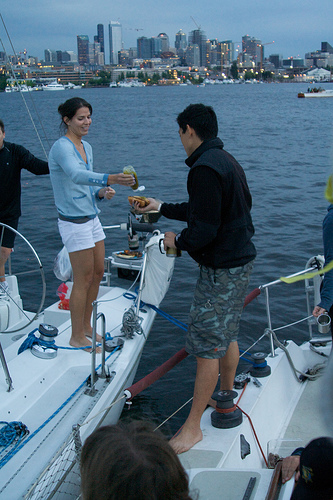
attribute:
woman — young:
[41, 101, 135, 348]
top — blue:
[47, 141, 105, 218]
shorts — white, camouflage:
[46, 217, 119, 251]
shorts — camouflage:
[189, 268, 248, 360]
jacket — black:
[159, 152, 277, 269]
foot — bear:
[165, 420, 207, 450]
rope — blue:
[144, 307, 184, 332]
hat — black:
[295, 434, 331, 500]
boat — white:
[294, 79, 332, 104]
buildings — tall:
[28, 33, 299, 74]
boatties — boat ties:
[210, 381, 280, 428]